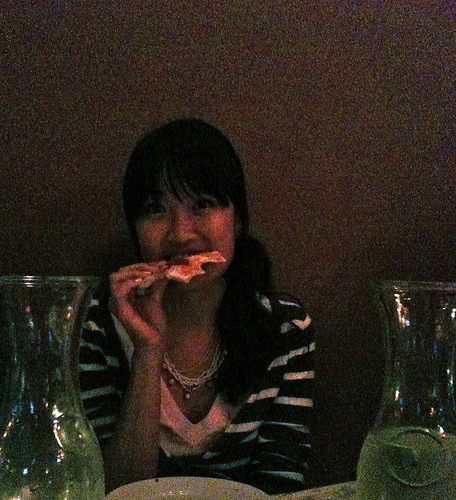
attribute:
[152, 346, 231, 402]
necklace — silver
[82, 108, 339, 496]
woman — eating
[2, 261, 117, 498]
vase — large, glass